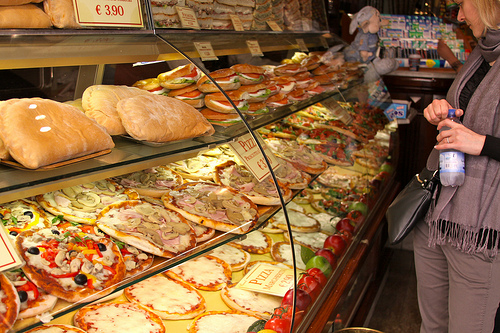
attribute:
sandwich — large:
[2, 89, 109, 170]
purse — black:
[386, 165, 441, 242]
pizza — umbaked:
[165, 180, 270, 247]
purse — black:
[374, 156, 459, 245]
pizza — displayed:
[116, 254, 255, 331]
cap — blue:
[447, 107, 457, 117]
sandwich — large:
[192, 65, 248, 96]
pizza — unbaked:
[95, 197, 195, 258]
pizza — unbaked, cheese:
[14, 222, 124, 303]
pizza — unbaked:
[159, 178, 257, 237]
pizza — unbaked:
[214, 159, 291, 206]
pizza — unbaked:
[127, 267, 205, 321]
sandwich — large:
[119, 86, 206, 138]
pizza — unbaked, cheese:
[212, 240, 252, 270]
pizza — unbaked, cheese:
[168, 250, 235, 294]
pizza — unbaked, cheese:
[122, 274, 206, 319]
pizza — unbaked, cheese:
[70, 296, 167, 330]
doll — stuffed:
[345, 0, 389, 75]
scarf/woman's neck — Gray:
[467, 27, 499, 100]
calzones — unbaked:
[1, 80, 213, 172]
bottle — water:
[432, 114, 477, 178]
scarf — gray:
[409, 42, 485, 250]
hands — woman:
[425, 97, 477, 155]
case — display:
[26, 48, 388, 306]